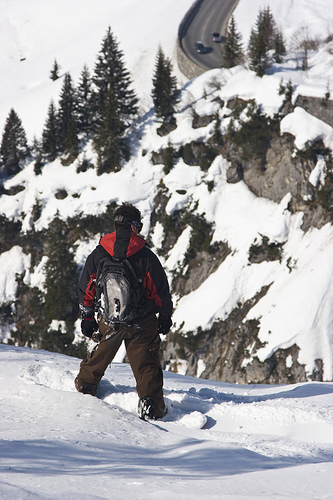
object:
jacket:
[81, 230, 172, 324]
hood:
[99, 230, 147, 258]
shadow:
[173, 380, 329, 407]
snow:
[3, 352, 329, 500]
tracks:
[33, 356, 72, 398]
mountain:
[2, 65, 330, 378]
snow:
[21, 162, 298, 243]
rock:
[144, 132, 329, 243]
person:
[76, 205, 174, 421]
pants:
[77, 320, 162, 400]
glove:
[157, 313, 173, 335]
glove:
[81, 316, 98, 338]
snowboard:
[24, 356, 209, 432]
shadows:
[6, 436, 321, 478]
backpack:
[93, 256, 144, 326]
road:
[178, 3, 242, 69]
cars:
[193, 40, 207, 54]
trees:
[76, 26, 140, 174]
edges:
[151, 146, 279, 178]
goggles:
[115, 215, 144, 233]